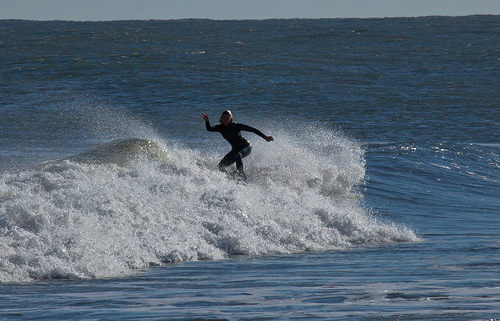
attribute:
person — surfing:
[199, 108, 275, 183]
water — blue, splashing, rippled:
[0, 16, 499, 319]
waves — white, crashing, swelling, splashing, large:
[1, 132, 498, 278]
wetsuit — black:
[201, 122, 266, 173]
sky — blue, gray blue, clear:
[1, 0, 500, 17]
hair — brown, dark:
[216, 111, 236, 123]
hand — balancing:
[201, 111, 211, 121]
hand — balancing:
[264, 135, 275, 143]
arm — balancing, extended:
[238, 121, 267, 139]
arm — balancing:
[206, 121, 222, 132]